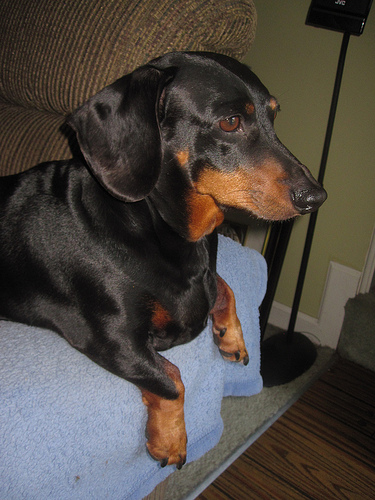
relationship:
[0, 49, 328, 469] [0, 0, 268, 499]
dog laying on couch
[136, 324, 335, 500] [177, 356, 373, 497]
carpet next to floor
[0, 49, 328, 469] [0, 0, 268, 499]
dog sitting on couch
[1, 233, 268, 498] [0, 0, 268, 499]
blanket on top of couch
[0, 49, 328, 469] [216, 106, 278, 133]
dog has eyes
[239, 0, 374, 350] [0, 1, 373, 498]
wall inside living room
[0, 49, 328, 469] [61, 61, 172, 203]
dog has ear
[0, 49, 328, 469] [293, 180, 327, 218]
dog has nose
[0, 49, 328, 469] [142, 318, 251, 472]
dog has paws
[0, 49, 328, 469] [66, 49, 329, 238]
dog has head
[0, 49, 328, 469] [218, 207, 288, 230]
dog has jaw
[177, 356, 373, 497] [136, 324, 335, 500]
floor ext to carpet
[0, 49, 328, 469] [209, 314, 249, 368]
dog has paw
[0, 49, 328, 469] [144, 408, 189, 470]
dog has paw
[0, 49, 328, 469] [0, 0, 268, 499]
dog sitting o couch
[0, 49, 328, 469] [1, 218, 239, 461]
dog sitting o couch arm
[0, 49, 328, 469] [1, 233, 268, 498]
dog o top of blanket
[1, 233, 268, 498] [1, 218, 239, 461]
blanket o top of couch arm